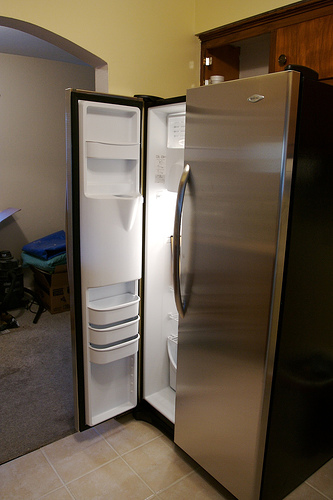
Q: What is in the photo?
A: Fridge.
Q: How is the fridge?
A: Open.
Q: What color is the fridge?
A: Silver.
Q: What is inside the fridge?
A: Nothing.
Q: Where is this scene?
A: In a kitchen.